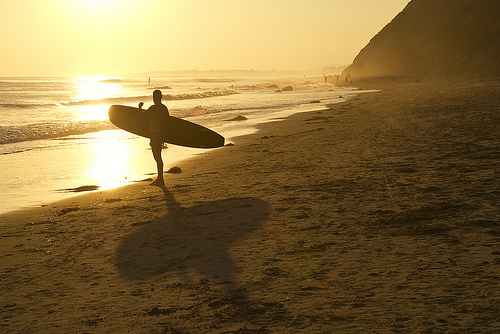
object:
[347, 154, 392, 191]
floor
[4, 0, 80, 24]
clouds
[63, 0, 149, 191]
sunset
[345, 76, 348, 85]
person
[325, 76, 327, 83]
person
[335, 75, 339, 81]
person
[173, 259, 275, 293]
sand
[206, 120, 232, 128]
wave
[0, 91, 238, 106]
wave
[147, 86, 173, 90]
wave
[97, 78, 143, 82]
wave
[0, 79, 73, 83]
wave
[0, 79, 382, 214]
ocean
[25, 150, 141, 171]
water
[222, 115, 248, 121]
rock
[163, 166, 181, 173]
rock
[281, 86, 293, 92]
rock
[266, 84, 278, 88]
rock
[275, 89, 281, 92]
rock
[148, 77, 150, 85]
paddle surfer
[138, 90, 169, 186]
surfer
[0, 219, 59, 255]
wet sand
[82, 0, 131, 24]
sun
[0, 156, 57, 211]
water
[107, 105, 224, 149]
surfboard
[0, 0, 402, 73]
sky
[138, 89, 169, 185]
man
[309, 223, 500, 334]
sand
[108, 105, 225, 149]
board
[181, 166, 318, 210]
sand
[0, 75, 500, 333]
ground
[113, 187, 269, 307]
shadow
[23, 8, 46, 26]
clouds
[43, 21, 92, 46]
clouds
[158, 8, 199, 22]
clouds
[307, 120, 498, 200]
sand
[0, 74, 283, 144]
beach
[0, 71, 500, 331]
beach